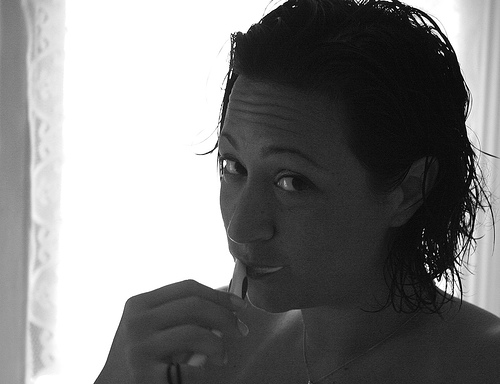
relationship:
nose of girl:
[220, 194, 278, 248] [86, 0, 499, 384]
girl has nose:
[86, 0, 499, 384] [222, 174, 274, 248]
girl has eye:
[86, 0, 499, 384] [266, 169, 324, 198]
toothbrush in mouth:
[186, 257, 251, 368] [226, 249, 287, 279]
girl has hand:
[86, 0, 499, 384] [95, 274, 269, 379]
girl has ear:
[86, 0, 499, 384] [379, 145, 444, 235]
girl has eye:
[86, 0, 499, 384] [270, 171, 320, 203]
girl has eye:
[86, 0, 499, 384] [217, 154, 249, 184]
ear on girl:
[389, 154, 441, 231] [171, 60, 461, 373]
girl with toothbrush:
[122, 30, 456, 369] [187, 256, 252, 340]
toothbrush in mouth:
[176, 260, 262, 379] [233, 264, 336, 324]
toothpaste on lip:
[241, 270, 270, 276] [233, 251, 292, 308]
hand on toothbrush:
[116, 281, 274, 371] [180, 254, 289, 376]